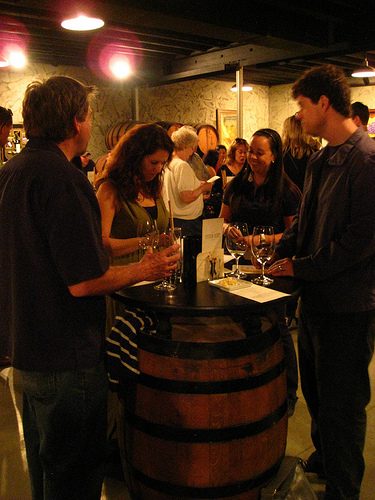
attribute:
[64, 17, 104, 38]
lights — bright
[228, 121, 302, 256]
lady — laughing